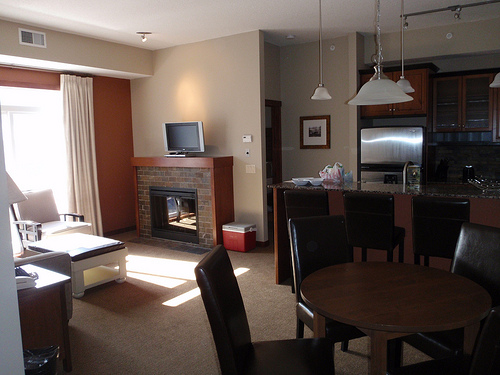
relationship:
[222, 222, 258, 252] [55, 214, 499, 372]
cooler on floor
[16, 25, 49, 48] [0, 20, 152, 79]
vent on wall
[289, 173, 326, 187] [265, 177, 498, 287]
bowls on counter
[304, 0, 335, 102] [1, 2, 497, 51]
light hanging from ceiling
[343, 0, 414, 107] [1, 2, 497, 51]
light hanging from ceiling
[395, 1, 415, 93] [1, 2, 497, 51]
light hanging from ceiling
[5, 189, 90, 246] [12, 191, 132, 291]
chair has frame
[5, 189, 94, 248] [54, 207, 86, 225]
chair has arm rest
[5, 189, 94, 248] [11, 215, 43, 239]
chair has arm rest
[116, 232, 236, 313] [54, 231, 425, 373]
sunlight shining on floor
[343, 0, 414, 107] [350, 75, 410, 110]
light has cover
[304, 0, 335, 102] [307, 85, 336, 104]
light has cover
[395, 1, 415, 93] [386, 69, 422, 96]
light has cover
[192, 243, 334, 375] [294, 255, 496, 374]
chair around table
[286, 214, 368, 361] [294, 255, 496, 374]
chair around table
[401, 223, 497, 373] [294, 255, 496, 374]
chair around table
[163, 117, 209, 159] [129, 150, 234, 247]
television on mantel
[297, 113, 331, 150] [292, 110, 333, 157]
picture on frame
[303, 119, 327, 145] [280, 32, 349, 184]
picture on wall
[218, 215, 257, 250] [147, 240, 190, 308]
cooler on floor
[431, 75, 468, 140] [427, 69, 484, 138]
glass on cabinets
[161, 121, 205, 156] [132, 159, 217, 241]
television on fireplace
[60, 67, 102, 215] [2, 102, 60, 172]
curtains on window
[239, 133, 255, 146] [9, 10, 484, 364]
thermostat in house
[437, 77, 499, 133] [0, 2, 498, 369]
cabinet in kitchen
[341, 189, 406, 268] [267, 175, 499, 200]
chair at counter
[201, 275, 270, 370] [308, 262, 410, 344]
chair at table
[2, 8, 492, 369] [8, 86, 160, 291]
room has natural light